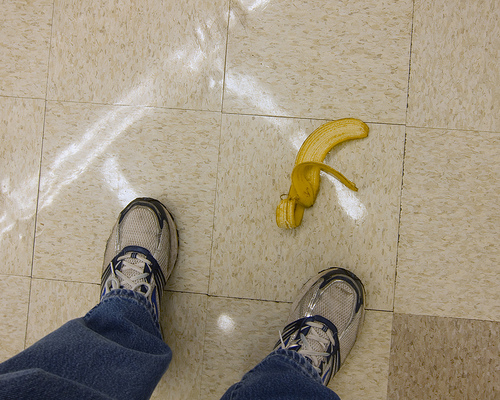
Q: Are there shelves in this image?
A: No, there are no shelves.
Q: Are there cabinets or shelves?
A: No, there are no shelves or cabinets.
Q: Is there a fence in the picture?
A: No, there are no fences.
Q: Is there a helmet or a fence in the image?
A: No, there are no fences or helmets.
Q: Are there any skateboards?
A: No, there are no skateboards.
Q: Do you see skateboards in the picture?
A: No, there are no skateboards.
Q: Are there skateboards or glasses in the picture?
A: No, there are no skateboards or glasses.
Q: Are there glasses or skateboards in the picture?
A: No, there are no skateboards or glasses.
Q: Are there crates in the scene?
A: No, there are no crates.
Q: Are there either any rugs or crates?
A: No, there are no crates or rugs.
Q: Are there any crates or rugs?
A: No, there are no crates or rugs.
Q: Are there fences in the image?
A: No, there are no fences.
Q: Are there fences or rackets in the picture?
A: No, there are no fences or rackets.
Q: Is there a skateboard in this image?
A: No, there are no skateboards.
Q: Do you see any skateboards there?
A: No, there are no skateboards.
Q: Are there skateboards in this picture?
A: No, there are no skateboards.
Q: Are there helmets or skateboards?
A: No, there are no skateboards or helmets.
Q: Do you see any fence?
A: No, there are no fences.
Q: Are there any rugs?
A: No, there are no rugs.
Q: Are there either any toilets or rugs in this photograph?
A: No, there are no rugs or toilets.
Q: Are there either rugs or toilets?
A: No, there are no rugs or toilets.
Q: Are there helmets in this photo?
A: No, there are no helmets.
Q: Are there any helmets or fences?
A: No, there are no helmets or fences.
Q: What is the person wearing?
A: The person is wearing shoes.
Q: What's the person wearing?
A: The person is wearing shoes.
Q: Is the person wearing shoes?
A: Yes, the person is wearing shoes.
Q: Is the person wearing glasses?
A: No, the person is wearing shoes.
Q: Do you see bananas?
A: Yes, there is a banana.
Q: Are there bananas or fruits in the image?
A: Yes, there is a banana.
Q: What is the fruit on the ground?
A: The fruit is a banana.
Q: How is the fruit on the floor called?
A: The fruit is a banana.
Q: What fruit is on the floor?
A: The fruit is a banana.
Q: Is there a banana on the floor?
A: Yes, there is a banana on the floor.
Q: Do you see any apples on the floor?
A: No, there is a banana on the floor.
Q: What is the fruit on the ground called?
A: The fruit is a banana.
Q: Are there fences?
A: No, there are no fences.